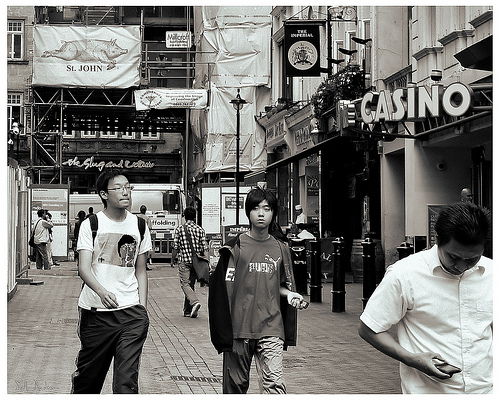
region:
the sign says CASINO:
[356, 75, 473, 130]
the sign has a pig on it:
[41, 32, 133, 74]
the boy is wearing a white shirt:
[349, 229, 497, 399]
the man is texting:
[423, 349, 459, 386]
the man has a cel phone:
[422, 355, 461, 382]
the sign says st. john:
[61, 60, 104, 77]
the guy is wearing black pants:
[58, 301, 156, 398]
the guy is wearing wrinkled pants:
[212, 333, 294, 398]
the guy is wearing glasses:
[100, 184, 140, 195]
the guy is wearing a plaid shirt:
[167, 205, 217, 322]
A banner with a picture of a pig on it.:
[29, 22, 141, 89]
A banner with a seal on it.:
[282, 20, 319, 76]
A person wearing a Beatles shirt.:
[70, 166, 150, 396]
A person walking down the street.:
[205, 181, 305, 396]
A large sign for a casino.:
[356, 80, 471, 120]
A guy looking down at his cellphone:
[355, 200, 495, 395]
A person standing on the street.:
[29, 208, 52, 269]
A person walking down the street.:
[170, 206, 210, 318]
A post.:
[360, 236, 378, 309]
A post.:
[330, 236, 347, 314]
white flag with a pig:
[35, 34, 135, 84]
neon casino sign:
[355, 84, 475, 129]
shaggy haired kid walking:
[189, 178, 328, 377]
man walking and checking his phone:
[364, 186, 487, 384]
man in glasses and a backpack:
[61, 162, 155, 393]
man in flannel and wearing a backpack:
[170, 203, 205, 319]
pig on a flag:
[39, 34, 129, 68]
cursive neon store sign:
[60, 149, 162, 170]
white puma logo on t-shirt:
[244, 251, 281, 278]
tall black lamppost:
[227, 83, 250, 214]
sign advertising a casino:
[353, 69, 475, 132]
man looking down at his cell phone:
[363, 197, 498, 385]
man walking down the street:
[59, 164, 159, 388]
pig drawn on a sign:
[27, 16, 147, 93]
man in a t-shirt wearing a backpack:
[62, 160, 161, 331]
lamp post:
[225, 78, 254, 230]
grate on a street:
[162, 365, 227, 390]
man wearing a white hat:
[285, 197, 312, 239]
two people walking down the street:
[52, 161, 316, 376]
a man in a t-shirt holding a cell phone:
[191, 183, 322, 374]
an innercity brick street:
[22, 16, 482, 383]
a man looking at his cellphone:
[349, 177, 490, 391]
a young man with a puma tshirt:
[202, 179, 312, 383]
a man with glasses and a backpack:
[72, 156, 157, 384]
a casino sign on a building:
[347, 68, 479, 203]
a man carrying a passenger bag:
[172, 197, 209, 324]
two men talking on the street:
[25, 201, 62, 273]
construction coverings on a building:
[15, 15, 270, 174]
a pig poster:
[28, 22, 142, 92]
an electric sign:
[61, 148, 186, 175]